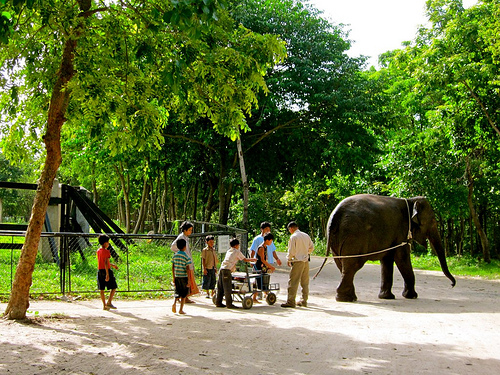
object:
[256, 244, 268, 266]
top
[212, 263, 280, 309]
cart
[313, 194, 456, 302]
elephant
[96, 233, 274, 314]
boy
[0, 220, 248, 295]
fence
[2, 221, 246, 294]
area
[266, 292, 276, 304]
wheel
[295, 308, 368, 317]
shadow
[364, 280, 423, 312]
ground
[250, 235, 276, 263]
blue shirt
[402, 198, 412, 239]
rope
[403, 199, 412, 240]
neck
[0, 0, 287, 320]
tree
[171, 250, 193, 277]
shirt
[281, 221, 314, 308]
handler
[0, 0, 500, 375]
park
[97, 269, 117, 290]
shorts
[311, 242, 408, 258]
rope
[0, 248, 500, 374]
road